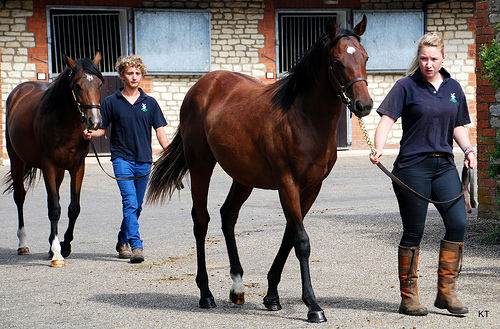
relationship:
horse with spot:
[1, 47, 113, 269] [346, 44, 356, 54]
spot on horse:
[346, 44, 356, 54] [141, 13, 374, 324]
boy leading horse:
[95, 65, 187, 276] [0, 51, 104, 268]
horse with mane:
[1, 47, 113, 269] [31, 59, 104, 165]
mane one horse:
[31, 59, 104, 165] [1, 47, 113, 269]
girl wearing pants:
[366, 29, 475, 316] [378, 146, 471, 250]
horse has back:
[166, 37, 411, 282] [219, 74, 272, 124]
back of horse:
[219, 74, 272, 124] [166, 37, 411, 282]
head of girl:
[408, 31, 448, 76] [368, 32, 479, 317]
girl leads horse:
[368, 32, 479, 317] [141, 13, 374, 324]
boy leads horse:
[82, 54, 171, 264] [1, 47, 113, 269]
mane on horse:
[266, 25, 359, 115] [141, 13, 374, 324]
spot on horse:
[84, 72, 94, 82] [141, 13, 374, 324]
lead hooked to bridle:
[357, 116, 476, 213] [324, 64, 368, 104]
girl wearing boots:
[368, 32, 479, 317] [382, 223, 499, 281]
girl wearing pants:
[368, 32, 479, 317] [391, 150, 469, 245]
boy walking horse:
[82, 54, 171, 264] [5, 50, 104, 267]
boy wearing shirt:
[82, 54, 171, 264] [102, 90, 170, 163]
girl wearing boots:
[368, 32, 479, 317] [388, 232, 481, 322]